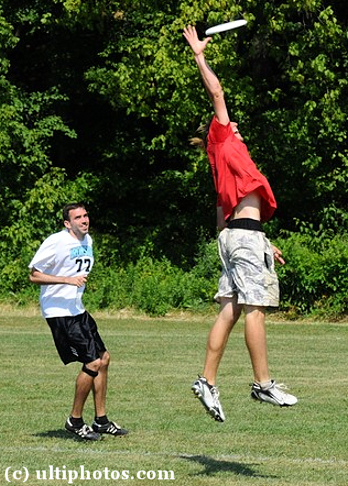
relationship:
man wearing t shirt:
[27, 206, 129, 441] [29, 230, 93, 320]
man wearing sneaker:
[27, 206, 129, 441] [64, 417, 100, 441]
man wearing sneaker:
[27, 206, 129, 441] [93, 420, 129, 438]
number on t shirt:
[75, 256, 91, 275] [29, 230, 93, 320]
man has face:
[27, 206, 129, 441] [71, 206, 89, 234]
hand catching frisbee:
[183, 23, 212, 56] [207, 17, 249, 35]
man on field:
[27, 206, 129, 441] [1, 313, 347, 483]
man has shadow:
[181, 21, 297, 421] [179, 451, 279, 480]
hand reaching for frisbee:
[183, 23, 212, 56] [207, 17, 249, 35]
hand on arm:
[183, 23, 212, 56] [195, 51, 229, 127]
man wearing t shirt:
[181, 21, 297, 421] [206, 117, 276, 223]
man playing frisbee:
[27, 206, 129, 441] [207, 17, 249, 35]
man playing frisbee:
[181, 21, 297, 421] [207, 17, 249, 35]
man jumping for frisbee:
[181, 21, 297, 421] [207, 17, 249, 35]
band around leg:
[81, 366, 99, 378] [55, 321, 103, 414]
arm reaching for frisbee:
[195, 51, 229, 127] [207, 17, 249, 35]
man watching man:
[27, 206, 129, 441] [181, 21, 297, 421]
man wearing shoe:
[181, 21, 297, 421] [191, 372, 226, 425]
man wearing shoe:
[181, 21, 297, 421] [248, 380, 299, 409]